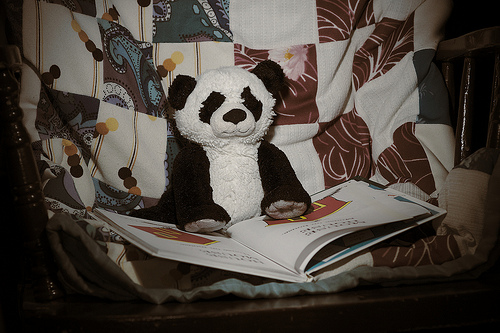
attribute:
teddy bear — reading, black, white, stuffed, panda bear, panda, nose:
[130, 59, 310, 235]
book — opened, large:
[85, 174, 449, 283]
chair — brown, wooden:
[0, 1, 499, 332]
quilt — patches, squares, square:
[0, 0, 499, 306]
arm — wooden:
[2, 44, 50, 263]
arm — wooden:
[434, 26, 499, 168]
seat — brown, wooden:
[13, 274, 499, 332]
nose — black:
[223, 110, 247, 126]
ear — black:
[167, 73, 198, 110]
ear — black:
[248, 59, 285, 97]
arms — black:
[172, 144, 211, 210]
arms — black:
[258, 139, 302, 187]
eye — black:
[246, 94, 255, 112]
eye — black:
[210, 100, 219, 112]